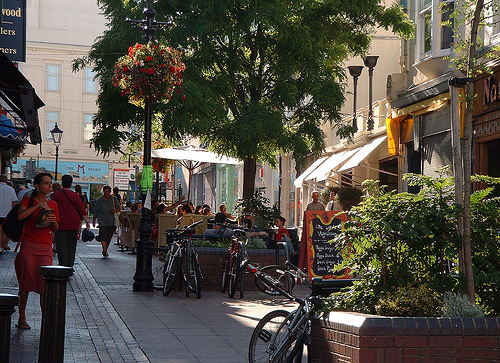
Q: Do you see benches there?
A: No, there are no benches.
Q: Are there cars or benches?
A: No, there are no benches or cars.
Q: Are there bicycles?
A: Yes, there is a bicycle.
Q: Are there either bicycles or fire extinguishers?
A: Yes, there is a bicycle.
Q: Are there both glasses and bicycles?
A: No, there is a bicycle but no glasses.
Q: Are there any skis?
A: No, there are no skis.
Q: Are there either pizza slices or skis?
A: No, there are no skis or pizza slices.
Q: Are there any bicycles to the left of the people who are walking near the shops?
A: Yes, there is a bicycle to the left of the people.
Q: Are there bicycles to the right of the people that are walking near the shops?
A: No, the bicycle is to the left of the people.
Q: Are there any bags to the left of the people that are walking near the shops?
A: No, there is a bicycle to the left of the people.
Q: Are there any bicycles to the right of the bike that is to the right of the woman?
A: Yes, there is a bicycle to the right of the bike.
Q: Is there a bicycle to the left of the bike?
A: No, the bicycle is to the right of the bike.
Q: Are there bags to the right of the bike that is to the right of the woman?
A: No, there is a bicycle to the right of the bike.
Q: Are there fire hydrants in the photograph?
A: No, there are no fire hydrants.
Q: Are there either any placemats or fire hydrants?
A: No, there are no fire hydrants or placemats.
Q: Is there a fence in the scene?
A: No, there are no fences.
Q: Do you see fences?
A: No, there are no fences.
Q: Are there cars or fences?
A: No, there are no fences or cars.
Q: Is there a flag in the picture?
A: Yes, there is a flag.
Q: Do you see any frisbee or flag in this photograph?
A: Yes, there is a flag.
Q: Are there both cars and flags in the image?
A: No, there is a flag but no cars.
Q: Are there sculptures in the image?
A: No, there are no sculptures.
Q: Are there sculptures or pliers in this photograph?
A: No, there are no sculptures or pliers.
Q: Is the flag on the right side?
A: Yes, the flag is on the right of the image.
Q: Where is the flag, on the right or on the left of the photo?
A: The flag is on the right of the image.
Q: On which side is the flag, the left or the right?
A: The flag is on the right of the image.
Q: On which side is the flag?
A: The flag is on the right of the image.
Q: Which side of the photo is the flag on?
A: The flag is on the right of the image.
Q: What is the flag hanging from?
A: The flag is hanging from the store.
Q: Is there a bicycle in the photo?
A: Yes, there is a bicycle.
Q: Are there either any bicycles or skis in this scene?
A: Yes, there is a bicycle.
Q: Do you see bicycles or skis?
A: Yes, there is a bicycle.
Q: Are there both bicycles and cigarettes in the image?
A: No, there is a bicycle but no cigarettes.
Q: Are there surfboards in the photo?
A: No, there are no surfboards.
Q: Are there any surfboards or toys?
A: No, there are no surfboards or toys.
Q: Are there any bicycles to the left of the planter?
A: Yes, there is a bicycle to the left of the planter.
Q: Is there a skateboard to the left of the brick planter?
A: No, there is a bicycle to the left of the planter.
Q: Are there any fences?
A: No, there are no fences.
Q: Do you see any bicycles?
A: Yes, there is a bicycle.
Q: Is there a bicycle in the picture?
A: Yes, there is a bicycle.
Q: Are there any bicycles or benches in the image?
A: Yes, there is a bicycle.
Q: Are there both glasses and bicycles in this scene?
A: No, there is a bicycle but no glasses.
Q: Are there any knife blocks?
A: No, there are no knife blocks.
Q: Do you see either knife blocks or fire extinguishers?
A: No, there are no knife blocks or fire extinguishers.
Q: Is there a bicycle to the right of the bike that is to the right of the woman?
A: Yes, there is a bicycle to the right of the bike.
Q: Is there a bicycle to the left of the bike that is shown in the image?
A: No, the bicycle is to the right of the bike.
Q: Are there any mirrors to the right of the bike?
A: No, there is a bicycle to the right of the bike.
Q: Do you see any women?
A: Yes, there is a woman.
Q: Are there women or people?
A: Yes, there is a woman.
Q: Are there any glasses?
A: No, there are no glasses.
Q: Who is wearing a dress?
A: The woman is wearing a dress.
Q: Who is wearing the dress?
A: The woman is wearing a dress.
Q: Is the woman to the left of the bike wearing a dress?
A: Yes, the woman is wearing a dress.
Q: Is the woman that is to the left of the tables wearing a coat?
A: No, the woman is wearing a dress.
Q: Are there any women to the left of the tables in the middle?
A: Yes, there is a woman to the left of the tables.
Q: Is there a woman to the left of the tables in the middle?
A: Yes, there is a woman to the left of the tables.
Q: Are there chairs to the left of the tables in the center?
A: No, there is a woman to the left of the tables.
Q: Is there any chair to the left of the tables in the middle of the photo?
A: No, there is a woman to the left of the tables.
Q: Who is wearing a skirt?
A: The woman is wearing a skirt.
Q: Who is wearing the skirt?
A: The woman is wearing a skirt.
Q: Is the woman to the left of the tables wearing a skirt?
A: Yes, the woman is wearing a skirt.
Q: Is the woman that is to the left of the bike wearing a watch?
A: No, the woman is wearing a skirt.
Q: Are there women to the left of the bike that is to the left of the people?
A: Yes, there is a woman to the left of the bike.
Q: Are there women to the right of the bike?
A: No, the woman is to the left of the bike.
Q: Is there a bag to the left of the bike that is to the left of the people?
A: No, there is a woman to the left of the bike.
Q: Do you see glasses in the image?
A: No, there are no glasses.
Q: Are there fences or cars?
A: No, there are no cars or fences.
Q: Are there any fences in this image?
A: No, there are no fences.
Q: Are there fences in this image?
A: No, there are no fences.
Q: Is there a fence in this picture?
A: No, there are no fences.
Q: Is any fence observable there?
A: No, there are no fences.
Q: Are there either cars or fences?
A: No, there are no fences or cars.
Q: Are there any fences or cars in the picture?
A: No, there are no fences or cars.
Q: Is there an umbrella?
A: Yes, there is an umbrella.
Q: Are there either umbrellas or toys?
A: Yes, there is an umbrella.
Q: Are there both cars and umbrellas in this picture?
A: No, there is an umbrella but no cars.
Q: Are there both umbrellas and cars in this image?
A: No, there is an umbrella but no cars.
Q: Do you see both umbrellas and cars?
A: No, there is an umbrella but no cars.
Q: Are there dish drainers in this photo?
A: No, there are no dish drainers.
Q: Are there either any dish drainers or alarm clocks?
A: No, there are no dish drainers or alarm clocks.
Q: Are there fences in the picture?
A: No, there are no fences.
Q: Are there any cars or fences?
A: No, there are no fences or cars.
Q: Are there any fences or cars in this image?
A: No, there are no fences or cars.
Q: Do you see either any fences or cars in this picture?
A: No, there are no fences or cars.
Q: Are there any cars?
A: No, there are no cars.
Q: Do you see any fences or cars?
A: No, there are no cars or fences.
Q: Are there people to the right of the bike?
A: Yes, there are people to the right of the bike.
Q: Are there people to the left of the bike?
A: No, the people are to the right of the bike.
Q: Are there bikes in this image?
A: Yes, there is a bike.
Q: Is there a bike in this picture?
A: Yes, there is a bike.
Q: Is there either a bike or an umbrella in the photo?
A: Yes, there is a bike.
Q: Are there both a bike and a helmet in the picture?
A: No, there is a bike but no helmets.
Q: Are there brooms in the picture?
A: No, there are no brooms.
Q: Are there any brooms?
A: No, there are no brooms.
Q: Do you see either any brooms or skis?
A: No, there are no brooms or skis.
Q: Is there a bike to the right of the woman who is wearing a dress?
A: Yes, there is a bike to the right of the woman.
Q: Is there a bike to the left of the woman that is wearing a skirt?
A: No, the bike is to the right of the woman.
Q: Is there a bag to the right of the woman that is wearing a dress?
A: No, there is a bike to the right of the woman.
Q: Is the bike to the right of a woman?
A: Yes, the bike is to the right of a woman.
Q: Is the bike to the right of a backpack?
A: No, the bike is to the right of a woman.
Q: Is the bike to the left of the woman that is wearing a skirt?
A: No, the bike is to the right of the woman.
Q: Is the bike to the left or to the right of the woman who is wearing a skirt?
A: The bike is to the right of the woman.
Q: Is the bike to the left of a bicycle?
A: Yes, the bike is to the left of a bicycle.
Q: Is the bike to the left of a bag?
A: No, the bike is to the left of a bicycle.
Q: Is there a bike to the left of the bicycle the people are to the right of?
A: Yes, there is a bike to the left of the bicycle.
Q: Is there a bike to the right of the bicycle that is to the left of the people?
A: No, the bike is to the left of the bicycle.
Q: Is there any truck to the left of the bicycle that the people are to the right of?
A: No, there is a bike to the left of the bicycle.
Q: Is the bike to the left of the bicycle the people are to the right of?
A: Yes, the bike is to the left of the bicycle.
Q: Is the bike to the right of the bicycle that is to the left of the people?
A: No, the bike is to the left of the bicycle.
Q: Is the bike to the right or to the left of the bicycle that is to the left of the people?
A: The bike is to the left of the bicycle.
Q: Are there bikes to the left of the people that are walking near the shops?
A: Yes, there is a bike to the left of the people.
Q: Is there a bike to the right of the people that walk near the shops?
A: No, the bike is to the left of the people.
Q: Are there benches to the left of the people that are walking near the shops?
A: No, there is a bike to the left of the people.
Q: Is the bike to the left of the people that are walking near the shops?
A: Yes, the bike is to the left of the people.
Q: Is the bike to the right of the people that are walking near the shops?
A: No, the bike is to the left of the people.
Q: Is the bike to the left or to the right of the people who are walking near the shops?
A: The bike is to the left of the people.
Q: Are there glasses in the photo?
A: No, there are no glasses.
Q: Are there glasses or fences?
A: No, there are no glasses or fences.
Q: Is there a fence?
A: No, there are no fences.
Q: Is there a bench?
A: No, there are no benches.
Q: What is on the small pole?
A: The poster is on the pole.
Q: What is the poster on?
A: The poster is on the pole.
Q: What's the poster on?
A: The poster is on the pole.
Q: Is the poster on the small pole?
A: Yes, the poster is on the pole.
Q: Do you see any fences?
A: No, there are no fences.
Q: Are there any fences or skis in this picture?
A: No, there are no fences or skis.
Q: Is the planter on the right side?
A: Yes, the planter is on the right of the image.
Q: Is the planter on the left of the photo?
A: No, the planter is on the right of the image.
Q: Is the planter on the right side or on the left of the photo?
A: The planter is on the right of the image.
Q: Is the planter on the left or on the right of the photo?
A: The planter is on the right of the image.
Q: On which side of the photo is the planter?
A: The planter is on the right of the image.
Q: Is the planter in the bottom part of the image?
A: Yes, the planter is in the bottom of the image.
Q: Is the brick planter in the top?
A: No, the planter is in the bottom of the image.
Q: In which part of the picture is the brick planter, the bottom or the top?
A: The planter is in the bottom of the image.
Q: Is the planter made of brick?
A: Yes, the planter is made of brick.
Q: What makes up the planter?
A: The planter is made of brick.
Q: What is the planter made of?
A: The planter is made of brick.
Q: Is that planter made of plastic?
A: No, the planter is made of brick.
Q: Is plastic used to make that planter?
A: No, the planter is made of brick.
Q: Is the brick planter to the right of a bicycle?
A: Yes, the planter is to the right of a bicycle.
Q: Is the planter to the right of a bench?
A: No, the planter is to the right of a bicycle.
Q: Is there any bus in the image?
A: No, there are no buses.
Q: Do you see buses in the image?
A: No, there are no buses.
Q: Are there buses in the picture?
A: No, there are no buses.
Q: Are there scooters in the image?
A: No, there are no scooters.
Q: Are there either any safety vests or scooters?
A: No, there are no scooters or safety vests.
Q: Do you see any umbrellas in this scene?
A: Yes, there is an umbrella.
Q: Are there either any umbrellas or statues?
A: Yes, there is an umbrella.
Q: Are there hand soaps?
A: No, there are no hand soaps.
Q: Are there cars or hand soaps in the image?
A: No, there are no hand soaps or cars.